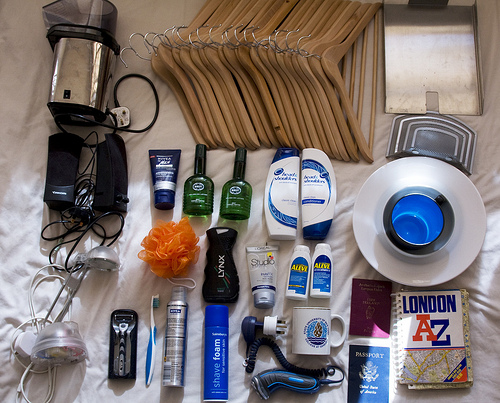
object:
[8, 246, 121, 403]
lamp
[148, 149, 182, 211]
toiletries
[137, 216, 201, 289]
sponge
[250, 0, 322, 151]
hangers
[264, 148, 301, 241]
bottles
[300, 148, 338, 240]
bottles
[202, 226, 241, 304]
shampoo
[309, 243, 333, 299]
pain medication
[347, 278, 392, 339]
documents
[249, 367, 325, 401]
shaver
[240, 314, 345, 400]
legs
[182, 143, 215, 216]
polish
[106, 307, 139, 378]
razor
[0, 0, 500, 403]
sheet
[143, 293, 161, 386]
toothbrush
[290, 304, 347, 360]
white mug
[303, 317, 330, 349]
blue design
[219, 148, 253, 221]
nail polish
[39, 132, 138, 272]
speakers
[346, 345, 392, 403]
passport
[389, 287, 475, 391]
map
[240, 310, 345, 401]
shaving implements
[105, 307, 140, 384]
shaving razor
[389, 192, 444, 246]
cup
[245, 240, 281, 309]
hair gel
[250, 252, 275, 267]
studio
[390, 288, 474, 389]
bottles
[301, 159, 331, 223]
label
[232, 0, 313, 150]
hangers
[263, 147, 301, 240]
shampoo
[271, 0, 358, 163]
hanger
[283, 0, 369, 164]
hanger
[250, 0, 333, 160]
hanger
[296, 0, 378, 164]
hanger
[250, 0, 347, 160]
hanger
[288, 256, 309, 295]
blue label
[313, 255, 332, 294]
blue label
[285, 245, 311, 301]
bottle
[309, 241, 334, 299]
bottle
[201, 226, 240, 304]
bottle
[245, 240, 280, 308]
tube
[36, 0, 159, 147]
razor